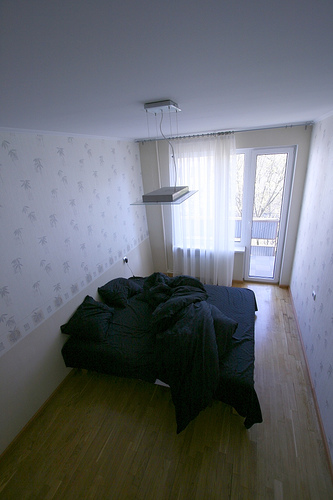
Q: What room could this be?
A: It is a bedroom.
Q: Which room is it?
A: It is a bedroom.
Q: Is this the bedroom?
A: Yes, it is the bedroom.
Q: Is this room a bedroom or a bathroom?
A: It is a bedroom.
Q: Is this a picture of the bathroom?
A: No, the picture is showing the bedroom.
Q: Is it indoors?
A: Yes, it is indoors.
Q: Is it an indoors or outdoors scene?
A: It is indoors.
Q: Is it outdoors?
A: No, it is indoors.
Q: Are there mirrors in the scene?
A: No, there are no mirrors.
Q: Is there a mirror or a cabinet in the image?
A: No, there are no mirrors or cabinets.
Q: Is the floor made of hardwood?
A: Yes, the floor is made of hardwood.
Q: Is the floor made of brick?
A: No, the floor is made of hardwood.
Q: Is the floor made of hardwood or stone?
A: The floor is made of hardwood.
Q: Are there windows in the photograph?
A: Yes, there is a window.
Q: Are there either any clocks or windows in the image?
A: Yes, there is a window.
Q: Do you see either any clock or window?
A: Yes, there is a window.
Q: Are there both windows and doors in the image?
A: Yes, there are both a window and a door.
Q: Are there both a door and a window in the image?
A: Yes, there are both a window and a door.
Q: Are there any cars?
A: No, there are no cars.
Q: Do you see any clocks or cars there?
A: No, there are no cars or clocks.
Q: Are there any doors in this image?
A: Yes, there is a door.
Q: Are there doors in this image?
A: Yes, there is a door.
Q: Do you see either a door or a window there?
A: Yes, there is a door.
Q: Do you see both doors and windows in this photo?
A: Yes, there are both a door and windows.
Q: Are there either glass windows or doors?
A: Yes, there is a glass door.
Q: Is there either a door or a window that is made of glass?
A: Yes, the door is made of glass.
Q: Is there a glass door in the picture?
A: Yes, there is a door that is made of glass.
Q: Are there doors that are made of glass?
A: Yes, there is a door that is made of glass.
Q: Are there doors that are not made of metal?
A: Yes, there is a door that is made of glass.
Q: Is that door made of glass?
A: Yes, the door is made of glass.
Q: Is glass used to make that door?
A: Yes, the door is made of glass.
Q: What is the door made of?
A: The door is made of glass.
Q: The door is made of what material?
A: The door is made of glass.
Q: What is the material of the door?
A: The door is made of glass.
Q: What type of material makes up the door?
A: The door is made of glass.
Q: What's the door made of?
A: The door is made of glass.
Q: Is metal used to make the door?
A: No, the door is made of glass.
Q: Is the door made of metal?
A: No, the door is made of glass.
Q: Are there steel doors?
A: No, there is a door but it is made of glass.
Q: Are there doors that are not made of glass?
A: No, there is a door but it is made of glass.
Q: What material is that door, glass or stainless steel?
A: The door is made of glass.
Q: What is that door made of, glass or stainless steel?
A: The door is made of glass.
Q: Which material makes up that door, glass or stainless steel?
A: The door is made of glass.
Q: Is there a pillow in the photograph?
A: Yes, there is a pillow.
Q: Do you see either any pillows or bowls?
A: Yes, there is a pillow.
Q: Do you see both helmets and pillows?
A: No, there is a pillow but no helmets.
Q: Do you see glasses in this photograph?
A: No, there are no glasses.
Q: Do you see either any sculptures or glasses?
A: No, there are no glasses or sculptures.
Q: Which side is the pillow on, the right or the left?
A: The pillow is on the left of the image.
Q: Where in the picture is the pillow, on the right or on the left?
A: The pillow is on the left of the image.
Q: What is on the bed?
A: The pillow is on the bed.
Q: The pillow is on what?
A: The pillow is on the bed.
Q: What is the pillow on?
A: The pillow is on the bed.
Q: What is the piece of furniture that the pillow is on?
A: The piece of furniture is a bed.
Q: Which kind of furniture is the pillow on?
A: The pillow is on the bed.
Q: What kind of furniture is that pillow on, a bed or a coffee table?
A: The pillow is on a bed.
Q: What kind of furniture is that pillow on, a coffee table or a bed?
A: The pillow is on a bed.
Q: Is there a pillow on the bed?
A: Yes, there is a pillow on the bed.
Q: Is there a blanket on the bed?
A: No, there is a pillow on the bed.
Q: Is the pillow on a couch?
A: No, the pillow is on the bed.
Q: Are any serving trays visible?
A: No, there are no serving trays.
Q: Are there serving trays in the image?
A: No, there are no serving trays.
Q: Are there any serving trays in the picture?
A: No, there are no serving trays.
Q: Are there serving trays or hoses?
A: No, there are no serving trays or hoses.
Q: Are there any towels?
A: No, there are no towels.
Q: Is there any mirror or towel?
A: No, there are no towels or mirrors.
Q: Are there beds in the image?
A: Yes, there is a bed.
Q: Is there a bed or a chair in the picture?
A: Yes, there is a bed.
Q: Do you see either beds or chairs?
A: Yes, there is a bed.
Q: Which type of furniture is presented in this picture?
A: The furniture is a bed.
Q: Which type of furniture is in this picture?
A: The furniture is a bed.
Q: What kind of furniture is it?
A: The piece of furniture is a bed.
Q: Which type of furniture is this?
A: That is a bed.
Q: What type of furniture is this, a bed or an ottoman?
A: That is a bed.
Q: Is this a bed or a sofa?
A: This is a bed.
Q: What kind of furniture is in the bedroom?
A: The piece of furniture is a bed.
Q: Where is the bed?
A: The bed is in the bedroom.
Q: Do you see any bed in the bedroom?
A: Yes, there is a bed in the bedroom.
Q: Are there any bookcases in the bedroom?
A: No, there is a bed in the bedroom.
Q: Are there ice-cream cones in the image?
A: No, there are no ice-cream cones.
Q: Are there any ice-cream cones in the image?
A: No, there are no ice-cream cones.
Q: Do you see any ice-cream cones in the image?
A: No, there are no ice-cream cones.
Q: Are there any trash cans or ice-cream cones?
A: No, there are no ice-cream cones or trash cans.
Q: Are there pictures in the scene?
A: No, there are no pictures.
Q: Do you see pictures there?
A: No, there are no pictures.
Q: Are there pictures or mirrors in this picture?
A: No, there are no pictures or mirrors.